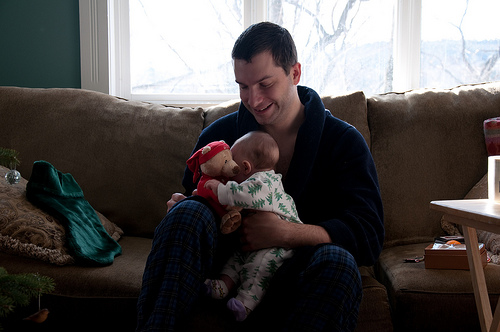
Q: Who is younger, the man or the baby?
A: The baby is younger than the man.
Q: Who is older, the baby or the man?
A: The man is older than the baby.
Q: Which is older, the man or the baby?
A: The man is older than the baby.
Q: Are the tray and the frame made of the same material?
A: Yes, both the tray and the frame are made of wood.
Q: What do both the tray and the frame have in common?
A: The material, both the tray and the frame are wooden.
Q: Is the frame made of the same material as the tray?
A: Yes, both the frame and the tray are made of wood.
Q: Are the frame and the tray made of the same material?
A: Yes, both the frame and the tray are made of wood.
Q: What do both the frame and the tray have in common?
A: The material, both the frame and the tray are wooden.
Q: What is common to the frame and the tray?
A: The material, both the frame and the tray are wooden.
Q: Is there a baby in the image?
A: Yes, there is a baby.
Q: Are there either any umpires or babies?
A: Yes, there is a baby.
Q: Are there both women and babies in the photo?
A: No, there is a baby but no women.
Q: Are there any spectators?
A: No, there are no spectators.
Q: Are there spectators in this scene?
A: No, there are no spectators.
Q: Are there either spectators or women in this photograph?
A: No, there are no spectators or women.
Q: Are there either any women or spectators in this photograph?
A: No, there are no spectators or women.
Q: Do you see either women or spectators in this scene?
A: No, there are no spectators or women.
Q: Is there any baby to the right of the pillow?
A: Yes, there is a baby to the right of the pillow.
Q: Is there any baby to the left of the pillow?
A: No, the baby is to the right of the pillow.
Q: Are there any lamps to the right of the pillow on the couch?
A: No, there is a baby to the right of the pillow.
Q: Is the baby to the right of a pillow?
A: Yes, the baby is to the right of a pillow.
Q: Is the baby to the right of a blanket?
A: No, the baby is to the right of a pillow.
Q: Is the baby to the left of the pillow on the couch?
A: No, the baby is to the right of the pillow.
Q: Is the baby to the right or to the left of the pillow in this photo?
A: The baby is to the right of the pillow.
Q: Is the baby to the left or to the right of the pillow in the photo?
A: The baby is to the right of the pillow.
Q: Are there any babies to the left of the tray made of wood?
A: Yes, there is a baby to the left of the tray.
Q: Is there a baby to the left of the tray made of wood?
A: Yes, there is a baby to the left of the tray.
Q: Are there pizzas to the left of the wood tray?
A: No, there is a baby to the left of the tray.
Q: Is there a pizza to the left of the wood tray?
A: No, there is a baby to the left of the tray.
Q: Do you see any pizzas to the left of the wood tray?
A: No, there is a baby to the left of the tray.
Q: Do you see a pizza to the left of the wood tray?
A: No, there is a baby to the left of the tray.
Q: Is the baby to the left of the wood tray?
A: Yes, the baby is to the left of the tray.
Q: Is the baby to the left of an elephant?
A: No, the baby is to the left of the tray.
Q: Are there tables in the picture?
A: Yes, there is a table.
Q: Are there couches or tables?
A: Yes, there is a table.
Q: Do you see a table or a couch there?
A: Yes, there is a table.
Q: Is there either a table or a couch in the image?
A: Yes, there is a table.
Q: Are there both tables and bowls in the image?
A: No, there is a table but no bowls.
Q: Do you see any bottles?
A: No, there are no bottles.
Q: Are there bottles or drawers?
A: No, there are no bottles or drawers.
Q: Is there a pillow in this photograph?
A: Yes, there is a pillow.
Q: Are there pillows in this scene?
A: Yes, there is a pillow.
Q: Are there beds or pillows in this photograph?
A: Yes, there is a pillow.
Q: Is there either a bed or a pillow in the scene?
A: Yes, there is a pillow.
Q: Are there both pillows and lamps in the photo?
A: No, there is a pillow but no lamps.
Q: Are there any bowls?
A: No, there are no bowls.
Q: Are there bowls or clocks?
A: No, there are no bowls or clocks.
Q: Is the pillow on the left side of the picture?
A: Yes, the pillow is on the left of the image.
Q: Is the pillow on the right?
A: No, the pillow is on the left of the image.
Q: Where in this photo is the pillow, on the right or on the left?
A: The pillow is on the left of the image.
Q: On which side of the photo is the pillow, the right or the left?
A: The pillow is on the left of the image.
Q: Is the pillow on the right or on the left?
A: The pillow is on the left of the image.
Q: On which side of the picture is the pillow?
A: The pillow is on the left of the image.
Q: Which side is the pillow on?
A: The pillow is on the left of the image.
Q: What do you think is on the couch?
A: The pillow is on the couch.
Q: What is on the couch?
A: The pillow is on the couch.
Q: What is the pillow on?
A: The pillow is on the couch.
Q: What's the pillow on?
A: The pillow is on the couch.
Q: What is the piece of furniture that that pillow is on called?
A: The piece of furniture is a couch.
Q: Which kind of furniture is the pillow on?
A: The pillow is on the couch.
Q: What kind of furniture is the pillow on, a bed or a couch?
A: The pillow is on a couch.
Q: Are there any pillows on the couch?
A: Yes, there is a pillow on the couch.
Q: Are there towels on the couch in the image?
A: No, there is a pillow on the couch.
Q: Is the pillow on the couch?
A: Yes, the pillow is on the couch.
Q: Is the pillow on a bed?
A: No, the pillow is on the couch.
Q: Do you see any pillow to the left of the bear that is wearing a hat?
A: Yes, there is a pillow to the left of the bear.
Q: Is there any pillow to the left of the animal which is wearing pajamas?
A: Yes, there is a pillow to the left of the bear.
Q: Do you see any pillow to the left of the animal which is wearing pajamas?
A: Yes, there is a pillow to the left of the bear.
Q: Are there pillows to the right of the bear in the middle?
A: No, the pillow is to the left of the bear.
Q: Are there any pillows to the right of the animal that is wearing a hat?
A: No, the pillow is to the left of the bear.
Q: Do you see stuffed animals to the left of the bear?
A: No, there is a pillow to the left of the bear.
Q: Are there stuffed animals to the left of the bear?
A: No, there is a pillow to the left of the bear.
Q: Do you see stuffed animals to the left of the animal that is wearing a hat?
A: No, there is a pillow to the left of the bear.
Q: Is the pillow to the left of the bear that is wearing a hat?
A: Yes, the pillow is to the left of the bear.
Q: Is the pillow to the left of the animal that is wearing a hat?
A: Yes, the pillow is to the left of the bear.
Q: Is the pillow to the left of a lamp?
A: No, the pillow is to the left of the bear.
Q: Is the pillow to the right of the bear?
A: No, the pillow is to the left of the bear.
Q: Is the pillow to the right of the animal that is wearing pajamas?
A: No, the pillow is to the left of the bear.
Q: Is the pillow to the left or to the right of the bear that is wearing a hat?
A: The pillow is to the left of the bear.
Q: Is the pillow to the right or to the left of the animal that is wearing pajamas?
A: The pillow is to the left of the bear.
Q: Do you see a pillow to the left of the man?
A: Yes, there is a pillow to the left of the man.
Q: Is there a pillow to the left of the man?
A: Yes, there is a pillow to the left of the man.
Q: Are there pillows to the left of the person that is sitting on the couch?
A: Yes, there is a pillow to the left of the man.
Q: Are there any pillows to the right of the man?
A: No, the pillow is to the left of the man.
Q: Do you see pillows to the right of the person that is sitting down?
A: No, the pillow is to the left of the man.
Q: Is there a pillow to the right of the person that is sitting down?
A: No, the pillow is to the left of the man.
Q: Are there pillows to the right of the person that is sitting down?
A: No, the pillow is to the left of the man.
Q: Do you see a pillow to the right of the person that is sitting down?
A: No, the pillow is to the left of the man.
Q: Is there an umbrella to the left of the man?
A: No, there is a pillow to the left of the man.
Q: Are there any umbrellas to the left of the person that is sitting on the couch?
A: No, there is a pillow to the left of the man.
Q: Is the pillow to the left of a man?
A: Yes, the pillow is to the left of a man.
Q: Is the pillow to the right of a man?
A: No, the pillow is to the left of a man.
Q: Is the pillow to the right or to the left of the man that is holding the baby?
A: The pillow is to the left of the man.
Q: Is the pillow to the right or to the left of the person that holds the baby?
A: The pillow is to the left of the man.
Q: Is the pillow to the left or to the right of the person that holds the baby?
A: The pillow is to the left of the man.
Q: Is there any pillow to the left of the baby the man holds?
A: Yes, there is a pillow to the left of the baby.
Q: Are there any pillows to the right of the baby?
A: No, the pillow is to the left of the baby.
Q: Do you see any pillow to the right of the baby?
A: No, the pillow is to the left of the baby.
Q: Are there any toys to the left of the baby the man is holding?
A: No, there is a pillow to the left of the baby.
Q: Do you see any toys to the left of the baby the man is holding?
A: No, there is a pillow to the left of the baby.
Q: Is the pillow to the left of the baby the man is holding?
A: Yes, the pillow is to the left of the baby.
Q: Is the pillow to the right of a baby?
A: No, the pillow is to the left of a baby.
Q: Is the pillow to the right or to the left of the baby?
A: The pillow is to the left of the baby.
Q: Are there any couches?
A: Yes, there is a couch.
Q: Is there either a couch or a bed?
A: Yes, there is a couch.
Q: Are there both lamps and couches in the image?
A: No, there is a couch but no lamps.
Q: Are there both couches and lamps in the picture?
A: No, there is a couch but no lamps.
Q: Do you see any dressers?
A: No, there are no dressers.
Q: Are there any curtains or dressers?
A: No, there are no dressers or curtains.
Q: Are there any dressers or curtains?
A: No, there are no dressers or curtains.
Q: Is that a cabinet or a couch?
A: That is a couch.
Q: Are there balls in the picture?
A: Yes, there is a ball.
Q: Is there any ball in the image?
A: Yes, there is a ball.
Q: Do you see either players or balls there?
A: Yes, there is a ball.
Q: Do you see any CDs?
A: No, there are no cds.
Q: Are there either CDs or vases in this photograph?
A: No, there are no CDs or vases.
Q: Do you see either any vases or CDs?
A: No, there are no CDs or vases.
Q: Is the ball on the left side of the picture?
A: Yes, the ball is on the left of the image.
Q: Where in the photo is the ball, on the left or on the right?
A: The ball is on the left of the image.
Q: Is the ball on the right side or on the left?
A: The ball is on the left of the image.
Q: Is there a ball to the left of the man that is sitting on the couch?
A: Yes, there is a ball to the left of the man.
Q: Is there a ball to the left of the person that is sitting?
A: Yes, there is a ball to the left of the man.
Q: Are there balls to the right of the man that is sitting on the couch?
A: No, the ball is to the left of the man.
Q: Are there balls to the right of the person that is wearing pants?
A: No, the ball is to the left of the man.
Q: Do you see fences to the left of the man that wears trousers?
A: No, there is a ball to the left of the man.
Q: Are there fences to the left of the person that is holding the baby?
A: No, there is a ball to the left of the man.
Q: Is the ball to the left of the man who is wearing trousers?
A: Yes, the ball is to the left of the man.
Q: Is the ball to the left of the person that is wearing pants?
A: Yes, the ball is to the left of the man.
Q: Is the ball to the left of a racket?
A: No, the ball is to the left of the man.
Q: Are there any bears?
A: Yes, there is a bear.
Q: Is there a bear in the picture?
A: Yes, there is a bear.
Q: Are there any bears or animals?
A: Yes, there is a bear.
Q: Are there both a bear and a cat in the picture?
A: No, there is a bear but no cats.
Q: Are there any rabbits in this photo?
A: No, there are no rabbits.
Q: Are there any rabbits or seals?
A: No, there are no rabbits or seals.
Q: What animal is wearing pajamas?
A: The bear is wearing pajamas.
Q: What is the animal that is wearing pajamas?
A: The animal is a bear.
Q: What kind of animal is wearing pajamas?
A: The animal is a bear.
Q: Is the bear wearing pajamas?
A: Yes, the bear is wearing pajamas.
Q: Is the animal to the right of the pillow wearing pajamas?
A: Yes, the bear is wearing pajamas.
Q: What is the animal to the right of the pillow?
A: The animal is a bear.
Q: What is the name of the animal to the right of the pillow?
A: The animal is a bear.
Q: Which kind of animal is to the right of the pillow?
A: The animal is a bear.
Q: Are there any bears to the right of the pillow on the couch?
A: Yes, there is a bear to the right of the pillow.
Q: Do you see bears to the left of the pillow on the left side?
A: No, the bear is to the right of the pillow.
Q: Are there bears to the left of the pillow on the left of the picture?
A: No, the bear is to the right of the pillow.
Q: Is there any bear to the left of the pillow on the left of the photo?
A: No, the bear is to the right of the pillow.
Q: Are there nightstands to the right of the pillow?
A: No, there is a bear to the right of the pillow.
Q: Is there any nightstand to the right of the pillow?
A: No, there is a bear to the right of the pillow.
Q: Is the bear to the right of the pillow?
A: Yes, the bear is to the right of the pillow.